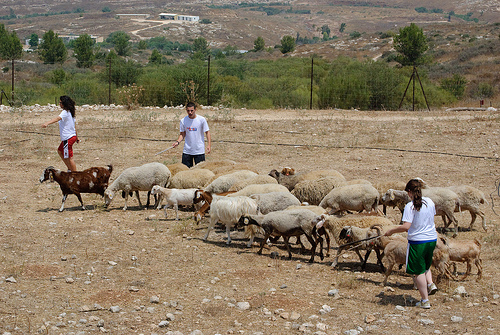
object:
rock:
[218, 271, 225, 275]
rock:
[289, 311, 302, 321]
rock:
[316, 323, 329, 331]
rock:
[328, 289, 340, 297]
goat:
[40, 165, 113, 213]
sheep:
[317, 179, 380, 215]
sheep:
[432, 238, 483, 285]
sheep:
[394, 184, 491, 233]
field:
[1, 99, 497, 333]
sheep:
[290, 176, 350, 206]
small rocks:
[139, 248, 197, 283]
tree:
[391, 22, 429, 111]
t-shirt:
[180, 114, 211, 155]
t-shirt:
[402, 196, 439, 243]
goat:
[236, 208, 324, 263]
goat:
[151, 185, 206, 222]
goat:
[204, 194, 257, 249]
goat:
[193, 190, 238, 224]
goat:
[104, 162, 172, 212]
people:
[382, 179, 439, 309]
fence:
[0, 56, 499, 111]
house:
[158, 12, 199, 21]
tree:
[96, 49, 125, 105]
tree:
[71, 33, 95, 69]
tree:
[0, 30, 23, 101]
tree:
[189, 37, 212, 60]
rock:
[66, 277, 75, 283]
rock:
[108, 260, 117, 266]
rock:
[280, 312, 289, 319]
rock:
[452, 286, 467, 296]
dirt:
[0, 108, 499, 335]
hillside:
[281, 22, 500, 107]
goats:
[380, 188, 461, 233]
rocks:
[50, 276, 57, 282]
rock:
[236, 302, 250, 311]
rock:
[321, 304, 331, 312]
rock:
[328, 289, 338, 297]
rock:
[421, 319, 435, 326]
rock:
[5, 276, 16, 283]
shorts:
[405, 241, 437, 275]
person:
[172, 102, 211, 169]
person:
[41, 95, 80, 173]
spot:
[69, 177, 73, 183]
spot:
[76, 180, 80, 185]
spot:
[88, 180, 94, 189]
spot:
[93, 172, 98, 179]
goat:
[166, 168, 215, 189]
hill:
[0, 4, 322, 52]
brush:
[471, 84, 495, 99]